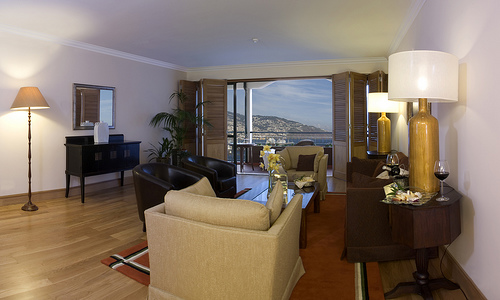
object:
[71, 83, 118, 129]
mirror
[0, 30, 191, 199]
wall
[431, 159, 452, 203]
glass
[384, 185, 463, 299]
endtable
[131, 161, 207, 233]
chair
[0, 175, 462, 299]
floor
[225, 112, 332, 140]
mountain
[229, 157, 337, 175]
balcony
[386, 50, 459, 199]
lamp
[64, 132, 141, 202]
cabinet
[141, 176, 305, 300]
armchair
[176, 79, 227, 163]
shutter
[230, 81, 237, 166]
door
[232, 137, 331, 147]
lake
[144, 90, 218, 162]
plant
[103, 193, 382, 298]
rug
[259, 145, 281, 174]
flower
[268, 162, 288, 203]
vase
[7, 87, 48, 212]
light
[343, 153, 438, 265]
sofa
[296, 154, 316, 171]
pillow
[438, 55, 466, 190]
shade